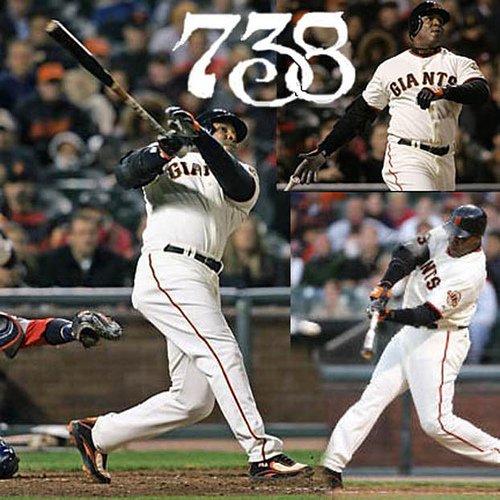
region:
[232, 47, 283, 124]
part of a number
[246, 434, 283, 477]
part of a shoe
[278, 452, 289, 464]
part of a lace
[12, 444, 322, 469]
green grass behind the batter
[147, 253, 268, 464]
red stripe stitched on pants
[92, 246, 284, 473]
batter wearing long white pants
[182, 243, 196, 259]
white belt loop sewn on pants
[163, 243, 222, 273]
black belt underneath belt loop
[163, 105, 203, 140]
batter is wearing black gloves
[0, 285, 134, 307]
gray metal railing behind batter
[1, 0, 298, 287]
crowd sitting in the stands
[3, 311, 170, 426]
low brick wall behind railing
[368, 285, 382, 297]
orange panel on top of the batter's gloves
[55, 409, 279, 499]
Person wearing tennis shoes.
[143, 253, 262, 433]
Person wearing white pants.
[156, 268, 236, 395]
Stripe down leg of pants.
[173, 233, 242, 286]
Person wearing black belt.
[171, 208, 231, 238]
Person wearing white shirt.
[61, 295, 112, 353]
Black mitt on catcher's hand.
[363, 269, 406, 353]
Person swinging baseball bat.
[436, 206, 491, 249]
Person wearing dark helmet.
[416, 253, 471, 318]
Person wearing white shirt.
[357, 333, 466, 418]
Person wearing white pants.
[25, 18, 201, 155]
the bat is raised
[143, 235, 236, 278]
the belt is black in colour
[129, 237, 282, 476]
the pant is white in colour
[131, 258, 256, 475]
the pant has a stripe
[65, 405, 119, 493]
a black sports shoe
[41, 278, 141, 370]
the hand has a glove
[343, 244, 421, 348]
the bat is ready to hit the ball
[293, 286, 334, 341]
the ball is white in colour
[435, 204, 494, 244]
the helmet is black in colour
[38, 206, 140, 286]
the man has a black jacket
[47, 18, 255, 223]
a man swinging a bat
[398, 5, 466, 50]
a man wearing a helmet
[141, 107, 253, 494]
a man wearing a baseball uniform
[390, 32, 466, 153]
a man wearing a white shirt with letters on it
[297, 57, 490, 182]
a man wearing a long sleeved black shirt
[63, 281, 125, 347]
a person wearing a baseball glove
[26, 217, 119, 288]
a man sitting on a bleacher seat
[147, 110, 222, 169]
a man wearing gloves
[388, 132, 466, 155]
a man wearing a black belt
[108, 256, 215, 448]
a man wearing white pants with a stripe